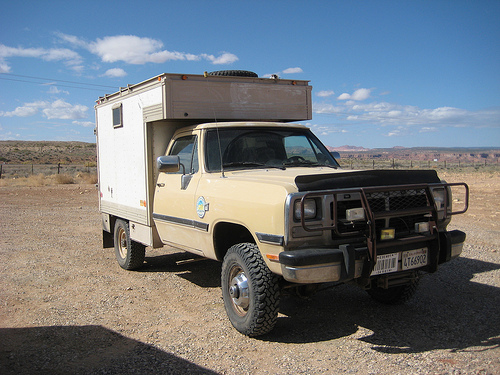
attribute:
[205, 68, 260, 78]
tire — spare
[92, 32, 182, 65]
cloud — white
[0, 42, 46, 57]
cloud — white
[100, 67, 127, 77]
cloud — white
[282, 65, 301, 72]
cloud — white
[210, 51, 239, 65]
cloud — white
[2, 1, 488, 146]
sky — blue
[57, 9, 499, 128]
sky — clear, blue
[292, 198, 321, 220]
headlight — white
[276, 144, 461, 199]
shield — black, Bug shield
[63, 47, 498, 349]
truck — yellow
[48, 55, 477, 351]
truck — yellow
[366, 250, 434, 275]
plates — license plates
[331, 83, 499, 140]
clouds — small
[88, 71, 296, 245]
camper — white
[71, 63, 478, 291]
truck — yellow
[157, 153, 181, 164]
mirror — rear view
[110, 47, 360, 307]
truck — yellow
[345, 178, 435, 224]
grill — front grill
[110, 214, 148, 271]
tire — back tire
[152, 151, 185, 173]
mirror — passenger side mirror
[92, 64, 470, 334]
truck — yellow, pickup truck, large